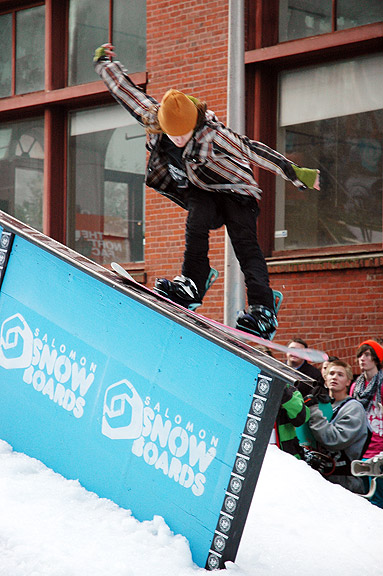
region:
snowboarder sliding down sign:
[135, 75, 262, 325]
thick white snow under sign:
[4, 391, 348, 569]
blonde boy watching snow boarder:
[317, 350, 356, 479]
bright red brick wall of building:
[136, 149, 371, 378]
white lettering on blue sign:
[108, 374, 216, 502]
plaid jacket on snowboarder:
[98, 55, 268, 190]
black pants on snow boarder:
[187, 202, 267, 311]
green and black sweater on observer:
[270, 388, 296, 447]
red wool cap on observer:
[363, 341, 382, 359]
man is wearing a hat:
[158, 88, 196, 135]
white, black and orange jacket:
[100, 60, 308, 208]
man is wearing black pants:
[171, 186, 274, 308]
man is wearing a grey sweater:
[309, 398, 365, 464]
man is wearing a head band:
[356, 339, 382, 363]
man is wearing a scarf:
[354, 372, 380, 408]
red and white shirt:
[348, 380, 380, 451]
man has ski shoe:
[235, 286, 283, 339]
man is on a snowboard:
[109, 255, 328, 369]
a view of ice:
[76, 511, 133, 553]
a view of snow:
[273, 519, 330, 569]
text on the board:
[115, 383, 234, 512]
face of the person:
[292, 347, 352, 395]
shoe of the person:
[138, 257, 257, 317]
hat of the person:
[349, 333, 381, 360]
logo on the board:
[89, 373, 184, 467]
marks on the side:
[197, 535, 240, 572]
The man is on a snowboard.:
[75, 43, 326, 372]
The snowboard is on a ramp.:
[1, 208, 329, 566]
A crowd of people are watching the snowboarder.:
[273, 335, 378, 509]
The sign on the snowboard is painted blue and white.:
[3, 236, 257, 567]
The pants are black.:
[172, 187, 282, 314]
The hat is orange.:
[151, 86, 200, 136]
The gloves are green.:
[91, 45, 116, 63]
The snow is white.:
[0, 446, 381, 575]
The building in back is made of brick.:
[1, 95, 381, 349]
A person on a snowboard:
[83, 30, 353, 381]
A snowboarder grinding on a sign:
[0, 12, 293, 571]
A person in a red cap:
[345, 332, 382, 462]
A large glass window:
[241, 29, 381, 266]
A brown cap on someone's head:
[148, 87, 202, 151]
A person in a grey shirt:
[305, 360, 370, 492]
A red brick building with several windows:
[2, 0, 382, 394]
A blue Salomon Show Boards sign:
[0, 214, 289, 574]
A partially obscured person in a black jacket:
[282, 336, 324, 388]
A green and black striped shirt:
[271, 374, 312, 462]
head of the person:
[121, 71, 225, 166]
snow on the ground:
[287, 507, 356, 552]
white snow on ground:
[254, 507, 332, 564]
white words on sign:
[103, 392, 237, 489]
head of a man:
[304, 348, 363, 399]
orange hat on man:
[141, 88, 208, 149]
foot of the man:
[221, 258, 306, 350]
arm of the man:
[238, 132, 311, 193]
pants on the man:
[139, 205, 286, 305]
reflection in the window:
[292, 110, 378, 217]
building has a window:
[66, 98, 143, 259]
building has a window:
[277, 55, 382, 248]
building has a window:
[277, 1, 335, 39]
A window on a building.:
[59, 102, 145, 267]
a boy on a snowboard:
[92, 41, 321, 335]